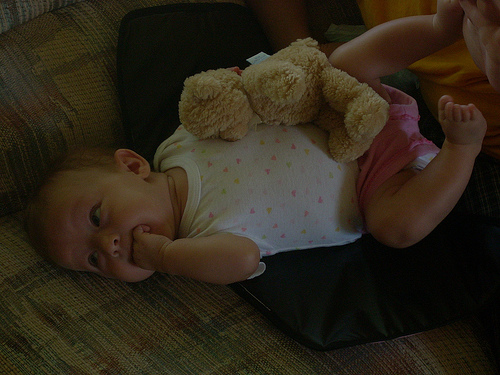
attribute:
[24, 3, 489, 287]
baby — laying, looking, white, female, barefoot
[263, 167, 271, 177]
heart — small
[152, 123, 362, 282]
onesie — white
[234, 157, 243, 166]
heart — small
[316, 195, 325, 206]
heart — small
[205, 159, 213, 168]
heart — pink, small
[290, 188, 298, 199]
heart — yellow, small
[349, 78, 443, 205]
shorts — pink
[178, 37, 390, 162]
teddy bear — tan, brown, small, stuffed, light brown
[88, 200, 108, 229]
eye — open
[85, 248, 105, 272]
eye — open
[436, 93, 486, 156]
foot — up, raised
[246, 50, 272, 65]
tag — white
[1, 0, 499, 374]
couch — light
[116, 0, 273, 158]
object — leathery, black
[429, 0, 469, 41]
foot — raised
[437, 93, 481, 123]
toes — curling